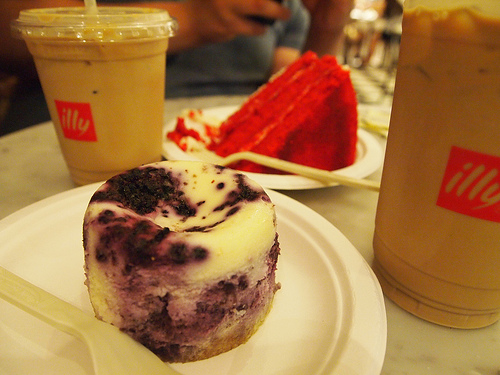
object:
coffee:
[370, 0, 499, 332]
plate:
[1, 167, 387, 375]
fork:
[1, 265, 170, 375]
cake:
[212, 51, 362, 170]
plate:
[158, 103, 385, 187]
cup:
[371, 0, 500, 333]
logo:
[49, 97, 99, 143]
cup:
[7, 0, 176, 180]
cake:
[82, 158, 278, 363]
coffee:
[21, 26, 190, 185]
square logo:
[434, 142, 500, 222]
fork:
[162, 138, 380, 192]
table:
[384, 318, 498, 375]